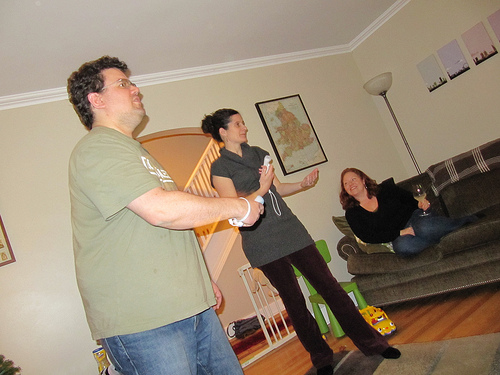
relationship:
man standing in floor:
[64, 55, 266, 375] [398, 312, 491, 372]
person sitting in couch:
[339, 167, 457, 257] [317, 172, 487, 286]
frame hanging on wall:
[255, 93, 335, 178] [323, 67, 362, 147]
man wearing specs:
[64, 55, 266, 375] [117, 74, 140, 91]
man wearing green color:
[64, 55, 266, 375] [67, 124, 218, 343]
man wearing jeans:
[13, 36, 267, 373] [91, 321, 256, 371]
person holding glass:
[339, 167, 457, 257] [409, 182, 431, 218]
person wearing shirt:
[339, 167, 457, 257] [340, 185, 415, 244]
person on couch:
[339, 167, 457, 257] [337, 138, 499, 315]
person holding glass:
[339, 167, 457, 257] [406, 173, 437, 223]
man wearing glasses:
[64, 55, 266, 375] [99, 76, 134, 90]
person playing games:
[200, 108, 405, 374] [256, 150, 280, 194]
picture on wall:
[255, 92, 331, 174] [4, 2, 496, 372]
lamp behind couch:
[359, 67, 437, 176] [332, 133, 499, 304]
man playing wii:
[64, 55, 266, 375] [249, 143, 287, 205]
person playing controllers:
[200, 108, 405, 374] [263, 155, 272, 174]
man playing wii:
[64, 55, 266, 375] [253, 147, 284, 190]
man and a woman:
[64, 55, 266, 375] [197, 91, 257, 162]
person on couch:
[339, 167, 457, 257] [342, 131, 496, 300]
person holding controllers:
[200, 108, 405, 374] [263, 155, 272, 174]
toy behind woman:
[354, 299, 400, 343] [189, 98, 410, 373]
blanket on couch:
[415, 133, 499, 190] [342, 135, 500, 309]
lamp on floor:
[359, 71, 437, 176] [425, 308, 467, 338]